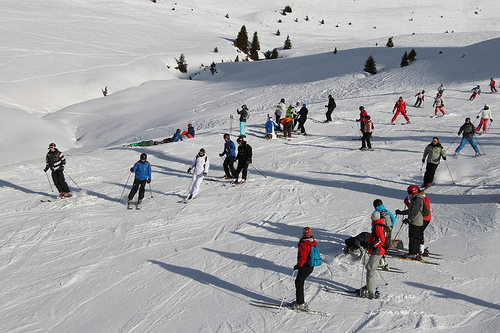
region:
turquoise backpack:
[308, 244, 323, 269]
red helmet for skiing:
[405, 182, 418, 199]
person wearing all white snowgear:
[185, 147, 210, 202]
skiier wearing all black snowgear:
[231, 134, 252, 186]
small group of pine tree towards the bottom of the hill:
[233, 23, 280, 61]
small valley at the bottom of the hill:
[35, 47, 284, 119]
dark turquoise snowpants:
[453, 135, 481, 155]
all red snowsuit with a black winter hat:
[388, 94, 413, 125]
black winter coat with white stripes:
[42, 148, 65, 173]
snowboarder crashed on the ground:
[342, 229, 405, 262]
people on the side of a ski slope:
[270, 170, 454, 312]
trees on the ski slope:
[226, 25, 291, 71]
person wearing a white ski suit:
[186, 143, 213, 200]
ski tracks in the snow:
[276, 157, 325, 219]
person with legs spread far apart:
[446, 113, 488, 161]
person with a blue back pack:
[308, 243, 324, 269]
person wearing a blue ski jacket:
[131, 137, 156, 190]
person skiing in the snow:
[39, 142, 79, 214]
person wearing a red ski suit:
[390, 88, 417, 133]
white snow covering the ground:
[29, 240, 136, 330]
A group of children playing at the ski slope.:
[258, 88, 318, 145]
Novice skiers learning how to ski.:
[383, 80, 456, 131]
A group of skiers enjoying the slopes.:
[115, 129, 257, 213]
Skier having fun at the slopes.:
[37, 138, 84, 209]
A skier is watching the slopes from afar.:
[277, 222, 327, 321]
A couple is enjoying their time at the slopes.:
[163, 119, 203, 144]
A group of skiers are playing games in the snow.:
[391, 73, 498, 133]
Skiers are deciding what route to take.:
[358, 180, 449, 310]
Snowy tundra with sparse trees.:
[154, 2, 461, 84]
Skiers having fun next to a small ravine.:
[31, 139, 218, 214]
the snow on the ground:
[0, 2, 498, 332]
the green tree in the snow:
[362, 53, 377, 75]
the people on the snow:
[39, 77, 498, 312]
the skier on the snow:
[178, 147, 209, 204]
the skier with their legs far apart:
[445, 117, 485, 159]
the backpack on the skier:
[308, 244, 323, 266]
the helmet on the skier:
[407, 183, 418, 195]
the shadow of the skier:
[148, 256, 288, 314]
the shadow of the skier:
[201, 244, 357, 293]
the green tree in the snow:
[233, 24, 248, 54]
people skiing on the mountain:
[21, 2, 494, 324]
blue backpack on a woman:
[309, 242, 321, 272]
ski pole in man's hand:
[120, 169, 129, 205]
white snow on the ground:
[28, 235, 235, 314]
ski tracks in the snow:
[151, 295, 182, 326]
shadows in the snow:
[141, 250, 283, 303]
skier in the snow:
[35, 135, 92, 212]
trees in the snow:
[234, 22, 295, 58]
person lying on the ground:
[343, 221, 373, 261]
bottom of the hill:
[272, 18, 473, 47]